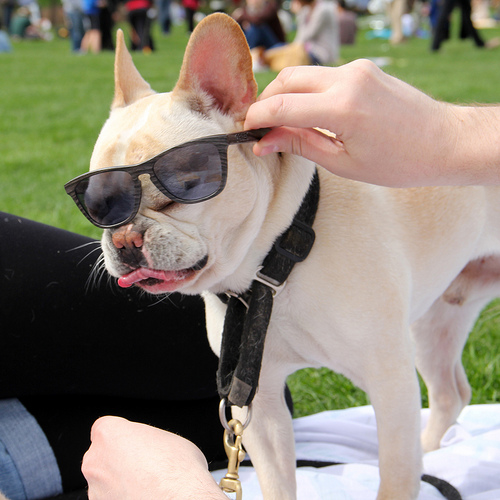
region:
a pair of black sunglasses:
[54, 118, 291, 230]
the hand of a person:
[73, 410, 235, 499]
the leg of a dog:
[368, 380, 427, 496]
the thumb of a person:
[250, 120, 340, 165]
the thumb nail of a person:
[256, 133, 282, 162]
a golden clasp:
[209, 412, 254, 498]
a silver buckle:
[216, 257, 287, 323]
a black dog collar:
[199, 172, 324, 416]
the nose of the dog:
[106, 226, 153, 251]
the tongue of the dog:
[112, 262, 184, 292]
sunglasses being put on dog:
[72, 126, 334, 221]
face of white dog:
[34, 54, 344, 274]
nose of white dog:
[74, 229, 202, 279]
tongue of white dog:
[111, 246, 198, 296]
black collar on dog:
[129, 223, 385, 433]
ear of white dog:
[162, 30, 328, 168]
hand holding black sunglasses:
[242, 59, 491, 208]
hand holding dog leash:
[61, 404, 223, 494]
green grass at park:
[28, 53, 145, 193]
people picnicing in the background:
[17, 0, 491, 42]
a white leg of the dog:
[362, 376, 425, 498]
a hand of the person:
[76, 410, 233, 498]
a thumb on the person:
[254, 125, 358, 178]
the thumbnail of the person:
[255, 137, 282, 161]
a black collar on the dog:
[201, 161, 332, 411]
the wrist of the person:
[436, 91, 498, 193]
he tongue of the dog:
[113, 261, 178, 286]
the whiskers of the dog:
[59, 230, 108, 296]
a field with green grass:
[22, 76, 86, 153]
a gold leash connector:
[212, 420, 253, 497]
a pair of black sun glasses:
[42, 124, 289, 215]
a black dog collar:
[210, 174, 351, 401]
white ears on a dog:
[67, 7, 258, 119]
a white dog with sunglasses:
[41, 61, 296, 318]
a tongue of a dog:
[110, 264, 201, 296]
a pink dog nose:
[102, 224, 152, 258]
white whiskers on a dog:
[62, 232, 112, 292]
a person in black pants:
[428, 0, 488, 54]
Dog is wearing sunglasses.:
[53, 131, 280, 230]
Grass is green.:
[3, 28, 102, 229]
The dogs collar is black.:
[219, 167, 341, 424]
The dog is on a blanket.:
[158, 370, 498, 497]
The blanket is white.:
[196, 392, 498, 497]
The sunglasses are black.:
[52, 120, 262, 230]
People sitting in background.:
[3, 0, 498, 77]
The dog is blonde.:
[81, 19, 498, 470]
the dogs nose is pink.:
[110, 219, 144, 253]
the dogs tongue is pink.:
[113, 266, 188, 287]